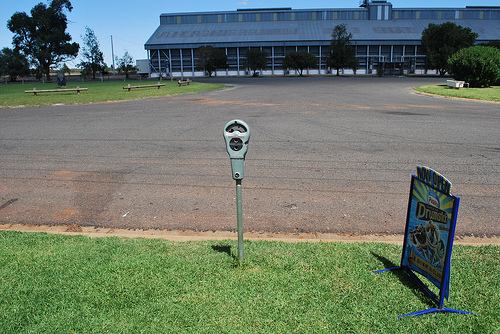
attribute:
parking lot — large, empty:
[6, 105, 499, 222]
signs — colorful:
[403, 161, 478, 311]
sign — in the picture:
[370, 162, 477, 319]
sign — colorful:
[398, 164, 460, 289]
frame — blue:
[391, 162, 462, 303]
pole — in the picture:
[235, 178, 247, 263]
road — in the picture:
[0, 77, 499, 238]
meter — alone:
[221, 115, 251, 183]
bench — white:
[443, 77, 465, 89]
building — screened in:
[142, 0, 429, 73]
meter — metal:
[218, 113, 250, 266]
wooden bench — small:
[120, 81, 170, 91]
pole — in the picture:
[235, 180, 245, 264]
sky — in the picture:
[103, 3, 152, 28]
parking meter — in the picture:
[222, 119, 252, 178]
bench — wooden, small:
[172, 68, 196, 95]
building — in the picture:
[131, 5, 498, 82]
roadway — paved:
[0, 105, 499, 235]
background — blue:
[403, 200, 453, 287]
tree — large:
[242, 46, 270, 80]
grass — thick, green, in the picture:
[2, 229, 484, 331]